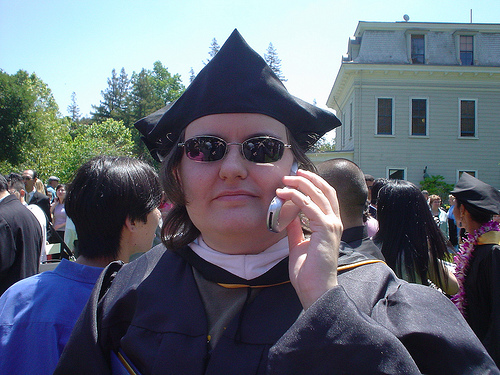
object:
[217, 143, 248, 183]
nose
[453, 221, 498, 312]
lei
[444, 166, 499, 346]
graduate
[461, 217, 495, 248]
neck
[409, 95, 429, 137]
window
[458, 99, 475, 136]
window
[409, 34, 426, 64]
window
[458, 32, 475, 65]
window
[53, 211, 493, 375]
robe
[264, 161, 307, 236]
phone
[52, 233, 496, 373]
gown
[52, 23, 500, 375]
person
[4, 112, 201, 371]
person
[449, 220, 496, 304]
lae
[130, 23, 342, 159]
cap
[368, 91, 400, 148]
window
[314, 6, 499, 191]
building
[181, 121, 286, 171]
sunglasses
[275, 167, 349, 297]
hand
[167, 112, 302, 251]
head